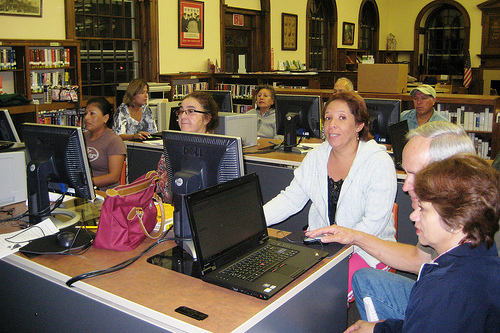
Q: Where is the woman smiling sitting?
A: At the table.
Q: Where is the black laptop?
A: On the table.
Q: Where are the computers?
A: On the long table.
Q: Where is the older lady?
A: Sitting at the table.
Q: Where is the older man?
A: Next to the lady.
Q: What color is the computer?
A: Black.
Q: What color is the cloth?
A: White.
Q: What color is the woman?
A: White.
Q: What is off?
A: The computer.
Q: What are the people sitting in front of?
A: Computers.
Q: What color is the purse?
A: Pink.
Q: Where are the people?
A: In a library.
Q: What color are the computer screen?
A: Black.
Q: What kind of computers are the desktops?
A: Dell.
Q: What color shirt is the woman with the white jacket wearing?
A: Black.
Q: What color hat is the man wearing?
A: White.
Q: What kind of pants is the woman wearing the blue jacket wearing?
A: Jeans.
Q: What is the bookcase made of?
A: Wood.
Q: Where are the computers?
A: On desks.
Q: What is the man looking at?
A: A computer.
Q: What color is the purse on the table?
A: Pink.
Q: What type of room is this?
A: A library.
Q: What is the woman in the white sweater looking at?
A: Camera.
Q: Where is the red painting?
A: On the left wall.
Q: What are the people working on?
A: Computers.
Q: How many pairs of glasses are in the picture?
A: One.